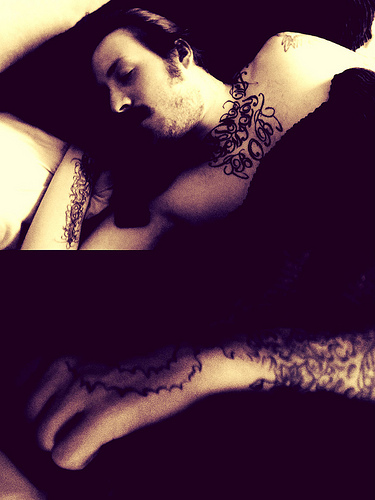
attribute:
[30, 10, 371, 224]
man — tattoed, sleeping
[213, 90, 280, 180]
tattoo — outlined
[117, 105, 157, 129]
mustache — thick, black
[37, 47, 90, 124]
pillow — black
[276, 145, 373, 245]
blanket — black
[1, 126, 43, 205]
pillow — white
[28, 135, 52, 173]
sheets — white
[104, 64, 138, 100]
eyes — closed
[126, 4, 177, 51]
hair — dark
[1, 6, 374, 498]
picture — indoors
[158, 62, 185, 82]
side burn — black